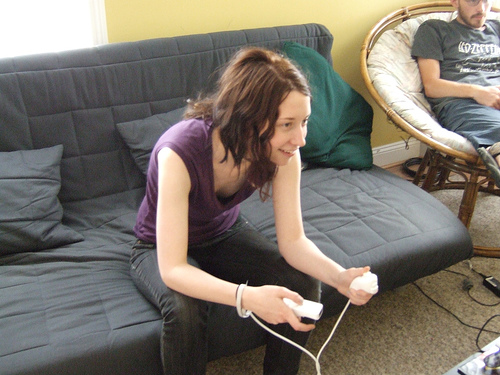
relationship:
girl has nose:
[131, 47, 380, 373] [292, 123, 305, 149]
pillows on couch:
[0, 39, 375, 254] [1, 23, 475, 373]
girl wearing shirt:
[131, 47, 380, 373] [133, 113, 273, 247]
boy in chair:
[412, 0, 500, 185] [359, 0, 499, 258]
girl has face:
[131, 47, 380, 373] [256, 90, 312, 164]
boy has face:
[412, 0, 500, 185] [449, 0, 494, 30]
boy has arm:
[409, 0, 500, 173] [414, 23, 499, 118]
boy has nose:
[409, 0, 500, 173] [477, 5, 483, 11]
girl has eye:
[131, 47, 380, 373] [278, 119, 291, 132]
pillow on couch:
[2, 143, 87, 257] [1, 23, 475, 373]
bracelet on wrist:
[234, 281, 253, 318] [219, 276, 263, 317]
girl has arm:
[131, 47, 380, 373] [154, 138, 317, 334]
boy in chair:
[409, 0, 500, 173] [359, 0, 499, 258]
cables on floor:
[411, 280, 499, 343] [388, 303, 453, 357]